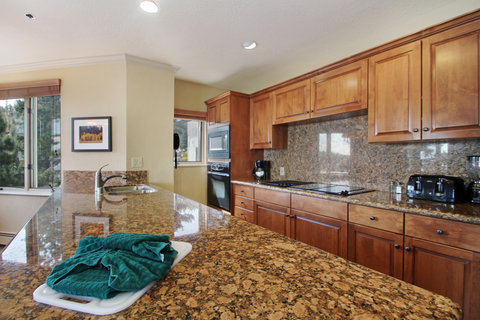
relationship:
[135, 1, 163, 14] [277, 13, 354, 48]
light on ceiling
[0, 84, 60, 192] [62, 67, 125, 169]
window on wall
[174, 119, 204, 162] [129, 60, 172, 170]
window on wall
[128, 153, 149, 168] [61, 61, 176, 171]
outlet on wall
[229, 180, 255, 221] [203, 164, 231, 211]
drawers next to oven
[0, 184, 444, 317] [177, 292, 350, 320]
counter table tiled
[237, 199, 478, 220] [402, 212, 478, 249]
these are drawer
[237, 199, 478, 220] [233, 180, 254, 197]
these are drawer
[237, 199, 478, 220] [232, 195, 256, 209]
these are drawer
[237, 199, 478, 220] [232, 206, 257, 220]
these are drawer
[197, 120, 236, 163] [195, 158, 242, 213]
microwave above oven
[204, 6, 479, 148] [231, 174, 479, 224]
cabinets above the counter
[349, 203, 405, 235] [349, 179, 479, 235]
drawer below counter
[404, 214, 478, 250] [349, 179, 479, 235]
drawer below counter